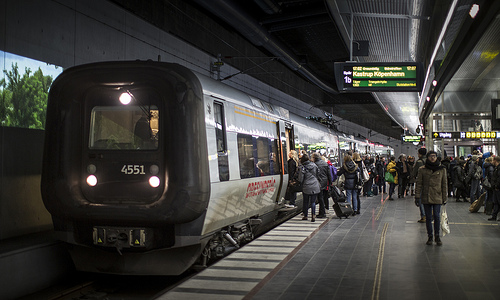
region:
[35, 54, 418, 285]
a train on track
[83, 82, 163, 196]
lights on front of train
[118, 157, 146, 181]
4551 on train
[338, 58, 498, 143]
sign for arrival of train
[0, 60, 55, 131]
trees on the left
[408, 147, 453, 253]
a man walking with white bag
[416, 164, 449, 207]
a brown wool coat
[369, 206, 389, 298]
yellow lines on ground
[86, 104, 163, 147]
windshield on front of train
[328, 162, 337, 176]
a purple bag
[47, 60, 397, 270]
black and grey train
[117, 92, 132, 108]
top light on train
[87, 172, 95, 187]
head light on train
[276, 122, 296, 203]
open door on train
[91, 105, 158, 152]
wind shield on train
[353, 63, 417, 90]
green and yellow sign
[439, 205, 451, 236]
white bag in hand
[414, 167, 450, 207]
brown polyester mans jacket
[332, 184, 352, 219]
black leather rolling suit case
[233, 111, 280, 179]
windows on train car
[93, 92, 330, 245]
black and silver train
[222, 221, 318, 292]
white stripe on platform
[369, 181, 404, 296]
yellow stripe on ground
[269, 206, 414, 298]
platform is dark grey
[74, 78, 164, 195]
white lights on train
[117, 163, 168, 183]
white numbers on train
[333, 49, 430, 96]
green and yellow sign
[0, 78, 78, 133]
green trees near train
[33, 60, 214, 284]
front of train is black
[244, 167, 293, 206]
red logo on side of train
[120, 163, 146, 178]
numbers in white coloring 4551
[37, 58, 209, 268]
back end of subway cart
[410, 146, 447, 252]
person standing holding a clear bag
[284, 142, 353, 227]
people with luggage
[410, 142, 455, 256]
person with heavy coat and scarf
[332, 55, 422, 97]
sign in foreign language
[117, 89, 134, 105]
bright light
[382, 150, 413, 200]
people standing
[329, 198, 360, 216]
black luggage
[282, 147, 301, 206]
blond woman getting on train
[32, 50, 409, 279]
Commuters boarding a train